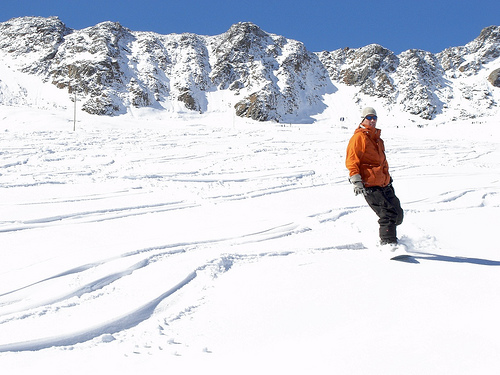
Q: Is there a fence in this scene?
A: No, there are no fences.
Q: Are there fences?
A: No, there are no fences.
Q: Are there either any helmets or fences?
A: No, there are no fences or helmets.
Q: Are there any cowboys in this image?
A: No, there are no cowboys.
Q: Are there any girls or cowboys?
A: No, there are no cowboys or girls.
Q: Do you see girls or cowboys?
A: No, there are no cowboys or girls.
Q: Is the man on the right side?
A: Yes, the man is on the right of the image.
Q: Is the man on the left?
A: No, the man is on the right of the image.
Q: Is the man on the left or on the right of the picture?
A: The man is on the right of the image.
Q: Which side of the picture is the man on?
A: The man is on the right of the image.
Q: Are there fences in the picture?
A: No, there are no fences.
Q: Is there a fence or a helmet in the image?
A: No, there are no fences or helmets.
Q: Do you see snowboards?
A: Yes, there is a snowboard.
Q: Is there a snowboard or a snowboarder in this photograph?
A: Yes, there is a snowboard.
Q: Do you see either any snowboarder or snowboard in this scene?
A: Yes, there is a snowboard.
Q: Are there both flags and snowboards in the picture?
A: No, there is a snowboard but no flags.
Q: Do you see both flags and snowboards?
A: No, there is a snowboard but no flags.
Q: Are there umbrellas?
A: No, there are no umbrellas.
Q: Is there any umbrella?
A: No, there are no umbrellas.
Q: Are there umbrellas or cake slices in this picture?
A: No, there are no umbrellas or cake slices.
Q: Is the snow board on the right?
A: Yes, the snow board is on the right of the image.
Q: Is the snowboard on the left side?
A: No, the snowboard is on the right of the image.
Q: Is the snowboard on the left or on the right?
A: The snowboard is on the right of the image.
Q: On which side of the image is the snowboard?
A: The snowboard is on the right of the image.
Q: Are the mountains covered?
A: Yes, the mountains are covered.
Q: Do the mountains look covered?
A: Yes, the mountains are covered.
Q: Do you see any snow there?
A: Yes, there is snow.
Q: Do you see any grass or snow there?
A: Yes, there is snow.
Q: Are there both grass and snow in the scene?
A: No, there is snow but no grass.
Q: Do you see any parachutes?
A: No, there are no parachutes.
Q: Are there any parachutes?
A: No, there are no parachutes.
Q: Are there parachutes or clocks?
A: No, there are no parachutes or clocks.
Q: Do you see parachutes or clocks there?
A: No, there are no parachutes or clocks.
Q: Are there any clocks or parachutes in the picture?
A: No, there are no parachutes or clocks.